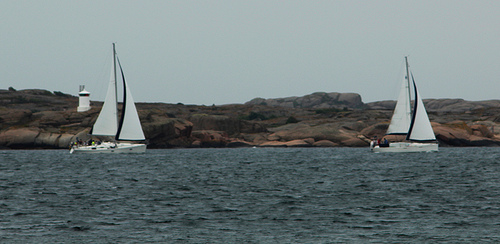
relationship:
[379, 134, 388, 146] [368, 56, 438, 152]
someone in boat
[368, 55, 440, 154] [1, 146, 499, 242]
boat in water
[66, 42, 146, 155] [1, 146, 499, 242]
boat in water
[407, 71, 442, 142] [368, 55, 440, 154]
sail on boat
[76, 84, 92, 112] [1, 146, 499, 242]
building near water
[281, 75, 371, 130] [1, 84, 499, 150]
rocks on land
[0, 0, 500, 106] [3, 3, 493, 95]
clouds in sky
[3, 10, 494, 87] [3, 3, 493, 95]
clouds in sky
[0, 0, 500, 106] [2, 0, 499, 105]
clouds in sky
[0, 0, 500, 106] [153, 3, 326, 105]
clouds in sky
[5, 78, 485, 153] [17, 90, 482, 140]
land has body